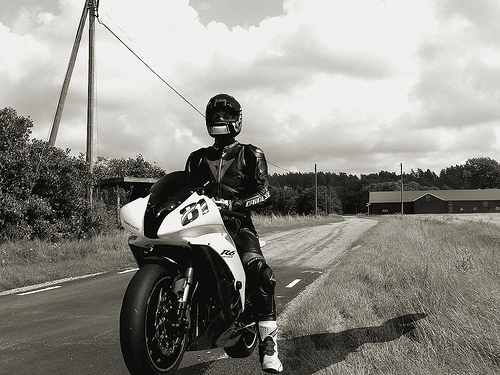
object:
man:
[182, 92, 284, 374]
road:
[0, 213, 380, 373]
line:
[17, 283, 64, 300]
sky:
[0, 20, 500, 177]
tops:
[12, 109, 500, 180]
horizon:
[2, 85, 499, 180]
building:
[367, 185, 499, 218]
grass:
[271, 209, 497, 373]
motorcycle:
[119, 170, 263, 373]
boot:
[254, 310, 285, 371]